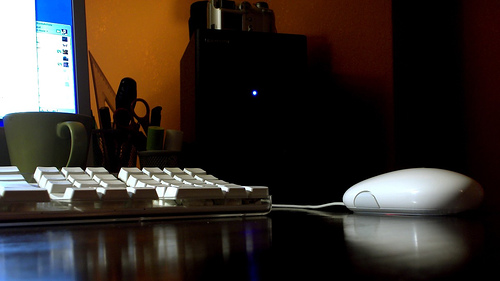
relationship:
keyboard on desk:
[1, 163, 271, 224] [20, 154, 249, 244]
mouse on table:
[337, 162, 486, 221] [1, 175, 496, 279]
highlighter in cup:
[165, 128, 182, 148] [138, 150, 174, 168]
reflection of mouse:
[343, 212, 465, 264] [341, 163, 479, 215]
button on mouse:
[338, 173, 378, 216] [349, 186, 382, 214]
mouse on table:
[273, 162, 486, 221] [2, 205, 499, 278]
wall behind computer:
[77, 2, 387, 182] [0, 0, 87, 163]